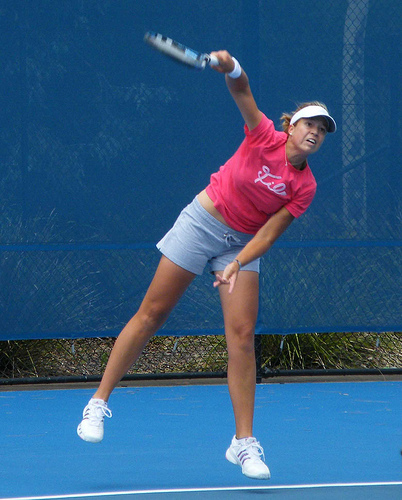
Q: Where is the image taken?
A: Tennis court.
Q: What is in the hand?
A: Racket.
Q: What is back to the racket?
A: Fence.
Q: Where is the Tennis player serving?
A: Endline.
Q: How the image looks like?
A: Good.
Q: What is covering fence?
A: Blue tarp.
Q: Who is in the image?
A: Tennis player.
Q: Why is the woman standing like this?
A: She just served.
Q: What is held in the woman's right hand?
A: Tennis racket.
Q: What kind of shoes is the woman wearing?
A: Tennis shoes.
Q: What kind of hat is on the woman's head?
A: A visor.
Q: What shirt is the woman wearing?
A: A pink shirt.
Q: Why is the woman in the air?
A: She just served the ball.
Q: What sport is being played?
A: Tennis.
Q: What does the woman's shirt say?
A: FILA.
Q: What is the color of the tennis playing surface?
A: Blue.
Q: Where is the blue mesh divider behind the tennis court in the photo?
A: Behind the woman.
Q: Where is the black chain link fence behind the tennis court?
A: Near woman wearing blue shorts.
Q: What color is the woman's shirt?
A: Pink.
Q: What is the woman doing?
A: Playing tennis.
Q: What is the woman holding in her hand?
A: A raquet.